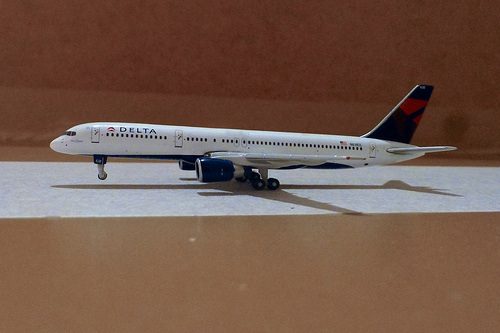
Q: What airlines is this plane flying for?
A: Delta.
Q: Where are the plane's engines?
A: Midway, beneath tthe plane's belly, on either side of the plane.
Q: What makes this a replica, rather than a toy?
A: The exacting detail,.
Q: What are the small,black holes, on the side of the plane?
A: Passenger windows.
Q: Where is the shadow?
A: Beneath the airplane.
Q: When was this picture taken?
A: Daytime.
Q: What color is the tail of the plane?
A: Blue.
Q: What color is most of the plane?
A: White.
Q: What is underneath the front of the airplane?
A: Landing gear.